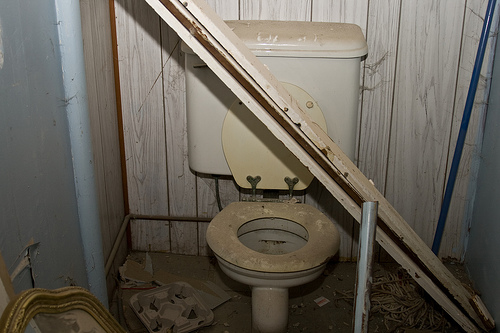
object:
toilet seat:
[204, 199, 341, 272]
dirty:
[225, 201, 294, 213]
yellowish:
[215, 218, 233, 254]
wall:
[107, 0, 500, 259]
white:
[375, 13, 383, 32]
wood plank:
[115, 0, 499, 333]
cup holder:
[130, 280, 217, 332]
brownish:
[170, 284, 194, 299]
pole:
[429, 0, 500, 258]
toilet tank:
[178, 19, 369, 177]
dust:
[226, 19, 364, 41]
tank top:
[181, 17, 370, 63]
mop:
[339, 273, 459, 333]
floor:
[0, 249, 500, 333]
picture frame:
[0, 284, 125, 333]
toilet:
[180, 14, 373, 333]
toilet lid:
[220, 80, 331, 191]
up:
[202, 81, 342, 273]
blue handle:
[429, 0, 500, 258]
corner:
[484, 0, 500, 107]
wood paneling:
[113, 1, 170, 255]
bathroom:
[0, 0, 500, 333]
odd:
[131, 250, 417, 323]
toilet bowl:
[234, 218, 307, 255]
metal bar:
[350, 201, 377, 333]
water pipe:
[212, 175, 224, 212]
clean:
[0, 29, 42, 85]